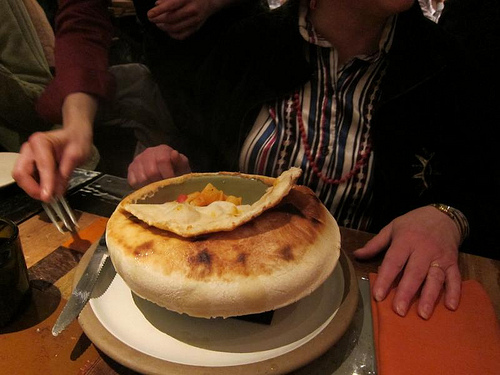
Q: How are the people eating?
A: With fork.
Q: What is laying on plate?
A: Knife.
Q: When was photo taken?
A: Daytime.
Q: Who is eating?
A: People.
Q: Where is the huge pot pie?
A: On plate.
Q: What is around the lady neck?
A: Necklace.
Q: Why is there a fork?
A: To eat.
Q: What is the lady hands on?
A: Table.